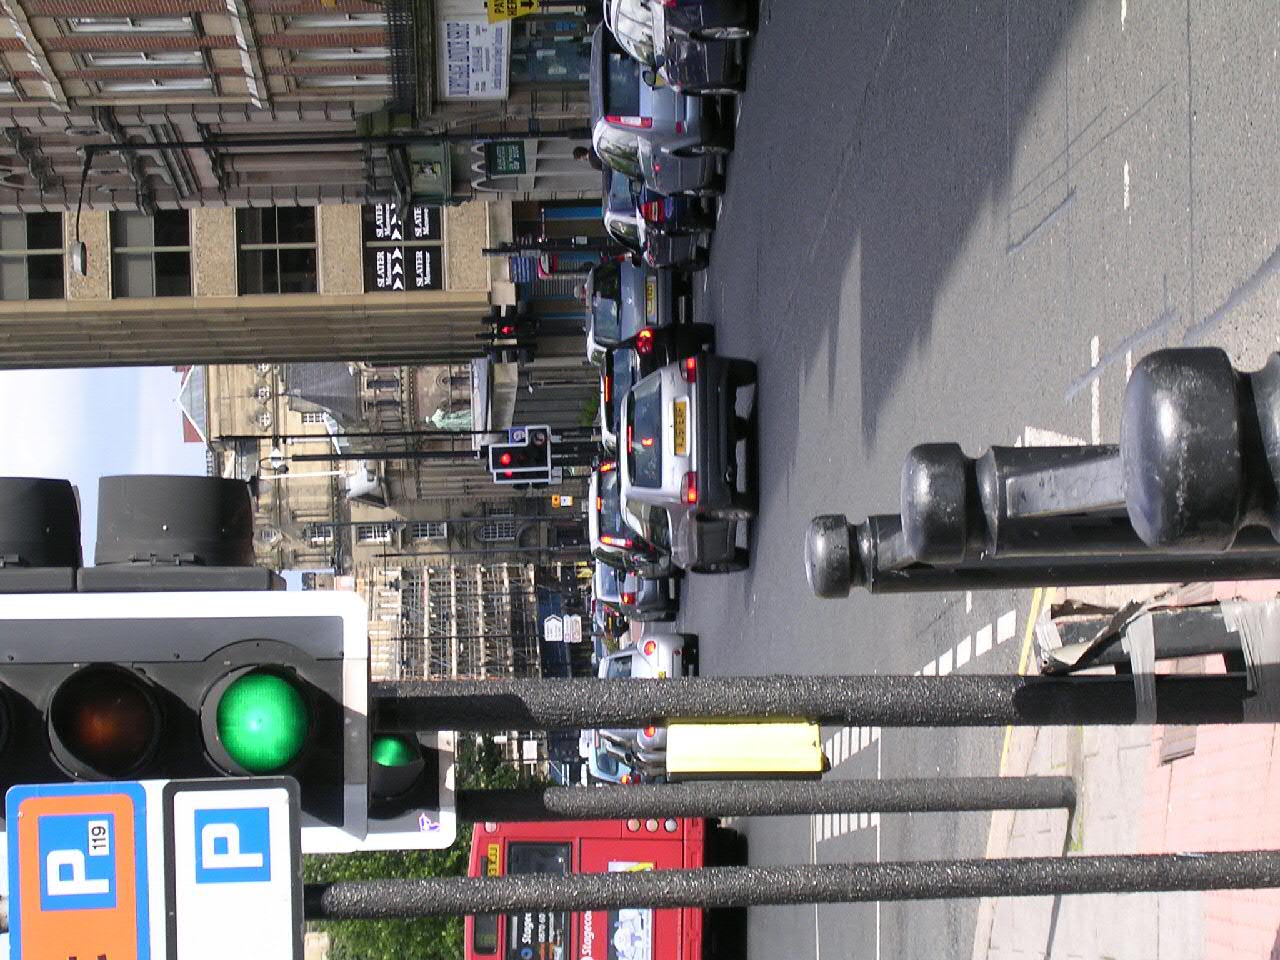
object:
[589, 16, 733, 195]
car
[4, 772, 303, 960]
signs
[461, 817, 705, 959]
red bus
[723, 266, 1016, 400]
road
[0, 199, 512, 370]
building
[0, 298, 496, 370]
wall